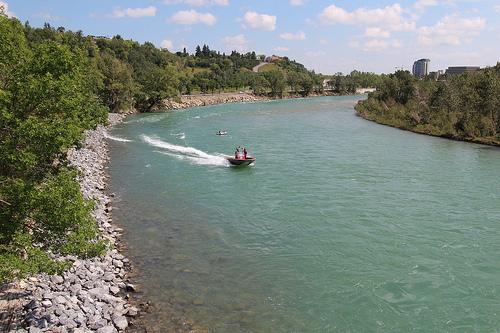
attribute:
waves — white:
[100, 128, 134, 149]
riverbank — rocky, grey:
[44, 115, 123, 332]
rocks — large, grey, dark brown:
[52, 283, 115, 322]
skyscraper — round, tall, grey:
[414, 58, 431, 81]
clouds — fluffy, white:
[316, 9, 478, 54]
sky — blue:
[5, 1, 497, 61]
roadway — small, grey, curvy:
[175, 87, 318, 96]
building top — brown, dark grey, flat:
[449, 66, 486, 77]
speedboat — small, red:
[225, 148, 257, 170]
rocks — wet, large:
[124, 218, 267, 332]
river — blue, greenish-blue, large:
[125, 96, 485, 331]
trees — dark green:
[375, 90, 497, 132]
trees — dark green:
[137, 64, 275, 86]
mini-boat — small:
[216, 131, 229, 139]